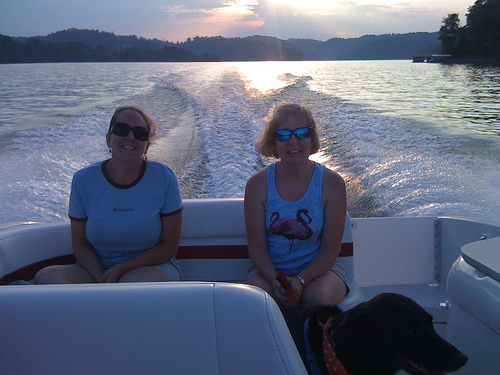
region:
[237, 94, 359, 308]
woman sitting on boat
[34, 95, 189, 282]
woman with sunglasses sitting on boat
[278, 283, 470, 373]
black lab dog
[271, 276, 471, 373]
dog wearing red scarf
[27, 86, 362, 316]
pair of women sitting on a boat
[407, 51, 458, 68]
docks on the shore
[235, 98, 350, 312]
women wearing flamingo shirt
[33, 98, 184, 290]
woman wearing sunglasses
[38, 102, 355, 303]
a pair of women wearing sunglasses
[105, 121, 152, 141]
black sunglasses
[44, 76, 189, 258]
Woman sitting at the back of a boat wearing a light blue shirt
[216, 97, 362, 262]
Woman with blonde hair wearing a light colored tank top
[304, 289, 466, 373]
Black dog looking sideways wearing a red bandanna on it's neck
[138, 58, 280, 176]
Frothy wake left behind in the water as a boat travels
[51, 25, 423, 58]
Bluish silhouette of mountains visible in the distance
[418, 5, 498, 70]
Stand of thick dark green trees on the shore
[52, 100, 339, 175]
Two women wearing sun glasses with the water behind them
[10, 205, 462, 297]
White back of a boat travelling on the water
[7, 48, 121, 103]
Calm blue water with a distant shore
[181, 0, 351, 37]
Light shining through thick white clouds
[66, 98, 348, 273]
two happy ladies on a boat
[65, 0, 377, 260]
woman riding a boat at sunset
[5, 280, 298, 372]
grey vinyl seat on a boat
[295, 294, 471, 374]
black lab with a red hankerchief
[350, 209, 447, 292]
small door on back of the boat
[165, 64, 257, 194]
white wake created by boat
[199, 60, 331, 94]
light of the setting sun on the water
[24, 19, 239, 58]
tree filled hills in the distance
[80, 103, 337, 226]
two ladies wearing sunglasses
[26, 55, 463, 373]
two women and their dog on a boat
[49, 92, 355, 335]
two women on a boat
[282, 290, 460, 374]
black dog on boat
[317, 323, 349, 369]
red bandana black dog is wearing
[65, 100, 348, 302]
two women wearing sunglasses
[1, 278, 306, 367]
white seat on boat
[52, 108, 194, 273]
woman wearing tshirt with black neck and arm rings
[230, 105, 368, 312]
woman wearing shirt with flamingos on it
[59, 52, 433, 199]
wake that boat is making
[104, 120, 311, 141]
sunglasses of the women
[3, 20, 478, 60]
mountain range in background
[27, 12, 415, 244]
two ladies on a boat at sunset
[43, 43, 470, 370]
two ladies and a dog on a boat at sunset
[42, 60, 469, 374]
two ladies and a black dog on a boat at sunset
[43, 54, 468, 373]
two ladies and a black lab on a boat at sunset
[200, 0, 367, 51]
setting sun partially concealed behind clouds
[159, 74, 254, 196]
wake created by boat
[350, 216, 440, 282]
small rear door of boat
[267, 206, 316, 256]
two pink flamingoes printed on shirt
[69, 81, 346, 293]
two happy women in sunglasses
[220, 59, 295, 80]
sunlight reflecting off water